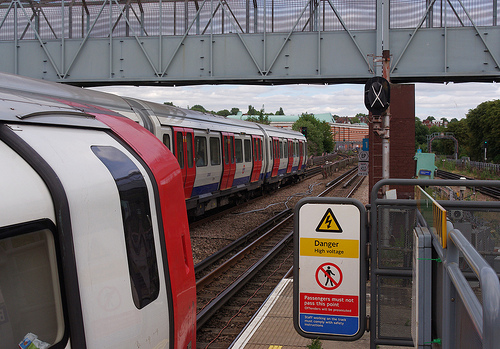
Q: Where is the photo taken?
A: Train station.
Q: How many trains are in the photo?
A: Two.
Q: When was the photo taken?
A: Daytime.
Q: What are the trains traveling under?
A: Bridge.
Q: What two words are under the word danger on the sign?
A: High voltage.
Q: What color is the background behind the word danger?
A: Yellow.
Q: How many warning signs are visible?
A: One.